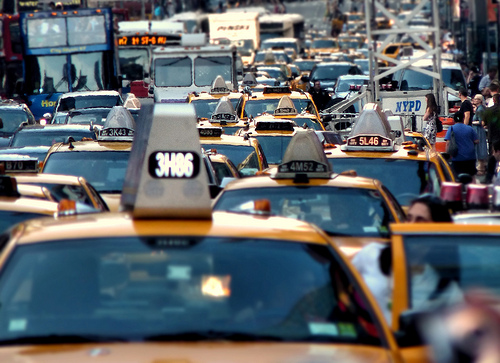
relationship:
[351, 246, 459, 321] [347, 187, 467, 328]
shirt on lady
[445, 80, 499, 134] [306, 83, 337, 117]
man in shirt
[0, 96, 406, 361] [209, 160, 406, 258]
taxi next to taxi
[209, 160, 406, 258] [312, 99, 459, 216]
taxi next to taxi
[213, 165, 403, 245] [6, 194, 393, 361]
taxi next to taxi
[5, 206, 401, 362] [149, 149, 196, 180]
cab with numbers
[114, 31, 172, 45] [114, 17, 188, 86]
numbers on front of bus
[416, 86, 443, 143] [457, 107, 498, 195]
woman wearing dress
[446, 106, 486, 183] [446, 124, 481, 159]
woman wearing shirt